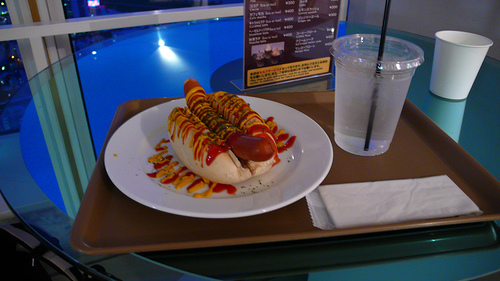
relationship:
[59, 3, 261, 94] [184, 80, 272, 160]
window next to hot dog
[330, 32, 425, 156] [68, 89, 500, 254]
beverage on a serving try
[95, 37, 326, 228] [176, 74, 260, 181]
plate with a hot dog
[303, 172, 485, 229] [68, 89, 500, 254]
napkin on a serving try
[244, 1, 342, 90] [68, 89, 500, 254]
lettering near a serving try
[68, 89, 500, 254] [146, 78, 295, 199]
serving try of fast-food meal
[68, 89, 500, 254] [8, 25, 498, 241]
serving try sitting on a table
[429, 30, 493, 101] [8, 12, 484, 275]
cup on a table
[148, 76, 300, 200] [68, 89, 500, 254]
fast-food meal on serving try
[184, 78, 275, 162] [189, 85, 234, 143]
hot dog has mustard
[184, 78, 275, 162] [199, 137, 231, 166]
hot dog has ketchup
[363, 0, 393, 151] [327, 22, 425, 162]
black straw in cup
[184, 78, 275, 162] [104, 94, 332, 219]
hot dog on plate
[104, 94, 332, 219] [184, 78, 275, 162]
plate with hot dog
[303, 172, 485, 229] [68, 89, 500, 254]
napkin on serving try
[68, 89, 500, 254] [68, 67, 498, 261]
serving try on table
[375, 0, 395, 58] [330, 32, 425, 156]
black straw in beverage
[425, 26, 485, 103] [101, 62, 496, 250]
cup on table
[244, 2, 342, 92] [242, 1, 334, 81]
lettering on menu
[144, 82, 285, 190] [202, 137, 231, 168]
hot dog with ketchup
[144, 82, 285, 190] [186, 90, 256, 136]
hot dog with mustard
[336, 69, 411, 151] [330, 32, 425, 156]
beverage in beverage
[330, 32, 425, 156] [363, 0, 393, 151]
beverage with black straw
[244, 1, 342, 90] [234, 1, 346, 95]
lettering in holder